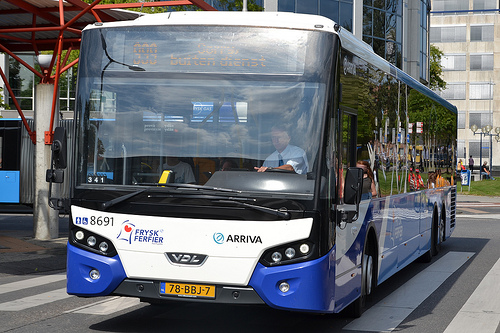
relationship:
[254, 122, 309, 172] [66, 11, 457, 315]
driver on bus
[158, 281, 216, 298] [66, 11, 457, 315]
license plate on bus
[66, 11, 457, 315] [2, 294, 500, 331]
bus on road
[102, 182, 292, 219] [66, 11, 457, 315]
wipers on bus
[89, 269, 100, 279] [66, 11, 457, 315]
headlight on bus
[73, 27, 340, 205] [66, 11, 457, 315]
windsheild on bus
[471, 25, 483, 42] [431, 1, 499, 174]
window on building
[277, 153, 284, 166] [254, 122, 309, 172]
tie on driver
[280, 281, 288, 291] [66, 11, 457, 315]
headlight on bus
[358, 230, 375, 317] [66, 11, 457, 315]
wheel on bus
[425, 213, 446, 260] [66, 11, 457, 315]
rear wheel on bus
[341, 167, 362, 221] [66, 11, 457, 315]
mirror on bus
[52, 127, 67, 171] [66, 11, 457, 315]
mirror on bus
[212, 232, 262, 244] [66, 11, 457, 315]
logo on bus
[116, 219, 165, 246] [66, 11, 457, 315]
frysk ferfier logo on bus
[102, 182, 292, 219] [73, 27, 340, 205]
wipers on windsheild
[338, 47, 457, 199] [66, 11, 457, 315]
side windows on bus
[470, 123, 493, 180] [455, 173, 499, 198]
lampost in grass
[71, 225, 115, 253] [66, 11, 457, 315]
three lights on bus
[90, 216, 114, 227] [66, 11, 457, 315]
bus number on bus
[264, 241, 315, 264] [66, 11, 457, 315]
three lights on bus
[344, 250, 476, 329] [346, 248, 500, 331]
white line on crosswalk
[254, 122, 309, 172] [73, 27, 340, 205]
driver behind windsheild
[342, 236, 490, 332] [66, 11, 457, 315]
shadow of bus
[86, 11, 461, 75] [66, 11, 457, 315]
roof of bus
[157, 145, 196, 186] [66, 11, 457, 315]
person on bus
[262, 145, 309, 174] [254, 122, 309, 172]
white shirt on driver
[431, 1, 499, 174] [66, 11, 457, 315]
building behind bus